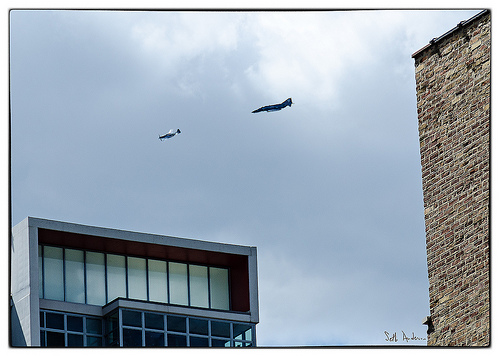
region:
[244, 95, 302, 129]
A fighter jet in the sky.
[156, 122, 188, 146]
A small aircraft in the sky.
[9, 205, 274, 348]
A modern style multi story building.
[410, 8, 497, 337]
A tall brick building.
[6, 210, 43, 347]
The side of a tall building.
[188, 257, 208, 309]
A window on the side of a building.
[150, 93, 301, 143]
A formation of aircraft.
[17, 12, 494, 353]
a scene during the day time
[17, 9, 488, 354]
a scene outside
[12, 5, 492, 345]
a image of the sky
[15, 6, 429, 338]
a sky with clouds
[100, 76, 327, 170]
two planes soar in the air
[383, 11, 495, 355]
a gray brick building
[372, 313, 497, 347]
a watermark on the corner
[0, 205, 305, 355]
a building with lots of windows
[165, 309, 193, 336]
a window that is clear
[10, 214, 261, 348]
Grey building with many windows.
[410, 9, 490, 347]
Tall brick tower.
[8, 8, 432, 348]
Blue sky with white clouds.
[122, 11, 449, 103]
White cloud going across the top sky.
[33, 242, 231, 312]
Ten white windows on a building.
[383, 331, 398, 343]
The name Seth.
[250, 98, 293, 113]
A long dark plane.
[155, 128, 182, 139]
Smaller plane in the air.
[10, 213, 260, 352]
A grey buildling.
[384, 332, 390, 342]
Letter S in Seth.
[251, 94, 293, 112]
a jet in the sky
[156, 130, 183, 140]
a gray jet flying in the air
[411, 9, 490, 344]
red bricks along the side of a building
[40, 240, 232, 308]
long panes on the front of a building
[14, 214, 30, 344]
the side of a gray building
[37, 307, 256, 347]
squares panes of glass in windows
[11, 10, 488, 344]
a heavily clouded sky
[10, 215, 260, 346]
a two story gray building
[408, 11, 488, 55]
the ledge of a brick building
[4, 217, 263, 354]
Gray building under planes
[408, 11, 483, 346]
Tall brick building near planes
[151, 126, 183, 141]
Small plane in the air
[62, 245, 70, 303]
Black slat on a window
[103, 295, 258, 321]
Gray edge of a window ledge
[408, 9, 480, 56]
Gutter on top of a building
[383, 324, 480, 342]
Photographer's signature on picture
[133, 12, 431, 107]
Bright clouds near planes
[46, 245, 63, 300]
Window glass between frames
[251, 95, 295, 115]
jet is flying above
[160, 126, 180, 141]
plane is flying above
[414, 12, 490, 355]
tall wall is brick